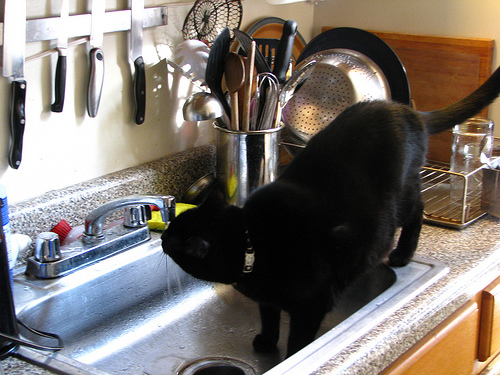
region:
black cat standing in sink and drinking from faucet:
[160, 67, 498, 354]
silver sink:
[6, 194, 446, 374]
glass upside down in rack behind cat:
[451, 117, 493, 209]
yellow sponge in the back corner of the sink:
[145, 202, 200, 230]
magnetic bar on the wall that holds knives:
[0, 7, 172, 50]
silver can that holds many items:
[213, 117, 283, 207]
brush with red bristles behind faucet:
[50, 217, 130, 242]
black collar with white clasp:
[237, 205, 257, 290]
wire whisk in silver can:
[253, 71, 278, 131]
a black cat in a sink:
[152, 66, 499, 338]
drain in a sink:
[183, 360, 253, 374]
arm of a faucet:
[79, 187, 178, 244]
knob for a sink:
[32, 231, 60, 263]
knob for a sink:
[124, 202, 152, 228]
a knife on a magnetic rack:
[127, 1, 147, 124]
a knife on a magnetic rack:
[86, 1, 108, 121]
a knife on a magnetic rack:
[50, 1, 73, 112]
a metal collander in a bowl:
[283, 46, 388, 144]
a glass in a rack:
[447, 115, 493, 200]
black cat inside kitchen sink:
[157, 67, 498, 357]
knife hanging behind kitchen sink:
[1, 6, 27, 168]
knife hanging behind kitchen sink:
[49, 6, 69, 111]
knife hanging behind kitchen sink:
[85, 6, 106, 117]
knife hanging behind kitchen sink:
[129, 6, 146, 124]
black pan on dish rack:
[290, 23, 411, 143]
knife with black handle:
[6, 76, 26, 166]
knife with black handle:
[48, 45, 66, 110]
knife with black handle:
[131, 56, 146, 123]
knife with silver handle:
[88, 47, 104, 119]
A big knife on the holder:
[115, 8, 165, 135]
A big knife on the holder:
[75, 1, 112, 140]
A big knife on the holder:
[40, 3, 72, 115]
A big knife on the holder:
[1, 3, 36, 167]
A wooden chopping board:
[426, 25, 486, 112]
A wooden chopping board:
[387, 35, 449, 150]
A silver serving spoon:
[174, 98, 241, 144]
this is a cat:
[126, 50, 497, 333]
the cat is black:
[135, 35, 493, 362]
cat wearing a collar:
[225, 198, 274, 299]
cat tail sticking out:
[397, 28, 499, 173]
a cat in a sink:
[111, 82, 488, 349]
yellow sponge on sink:
[137, 175, 197, 239]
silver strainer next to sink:
[266, 31, 406, 175]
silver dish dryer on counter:
[268, 107, 493, 227]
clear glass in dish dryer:
[443, 107, 493, 207]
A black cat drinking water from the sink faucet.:
[125, 51, 498, 328]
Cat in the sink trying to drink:
[83, 65, 485, 355]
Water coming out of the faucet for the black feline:
[22, 140, 204, 351]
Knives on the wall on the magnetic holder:
[2, 5, 207, 185]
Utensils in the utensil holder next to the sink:
[150, 10, 330, 176]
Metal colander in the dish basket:
[277, 15, 427, 167]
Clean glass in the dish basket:
[438, 88, 493, 239]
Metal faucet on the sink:
[27, 170, 208, 290]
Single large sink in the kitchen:
[12, 180, 469, 373]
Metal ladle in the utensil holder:
[152, 73, 302, 160]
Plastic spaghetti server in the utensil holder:
[157, 27, 260, 135]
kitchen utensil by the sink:
[223, 47, 243, 128]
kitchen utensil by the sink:
[236, 37, 253, 123]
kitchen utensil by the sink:
[250, 68, 275, 131]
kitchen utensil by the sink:
[265, 15, 296, 130]